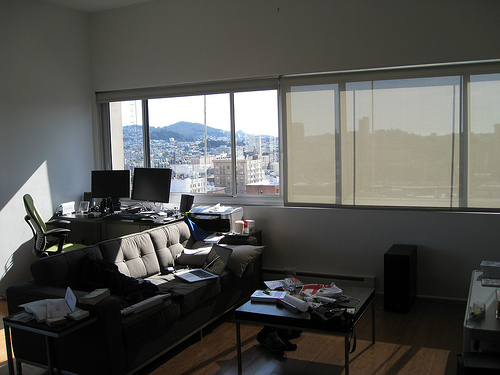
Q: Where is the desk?
A: By the window.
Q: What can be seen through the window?
A: The city.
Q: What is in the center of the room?
A: A coffee table.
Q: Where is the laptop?
A: On the couch.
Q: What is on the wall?
A: Windows.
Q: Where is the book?
A: On the table.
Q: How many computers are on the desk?
A: Two.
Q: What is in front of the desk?
A: A chair.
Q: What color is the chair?
A: Green.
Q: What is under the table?
A: Shoes.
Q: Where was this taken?
A: Living room.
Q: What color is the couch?
A: Black.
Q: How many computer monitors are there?
A: 2.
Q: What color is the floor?
A: Brown.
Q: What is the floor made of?
A: Wood.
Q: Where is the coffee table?
A: In front of the couch.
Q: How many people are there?
A: 0.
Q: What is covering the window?
A: Shade.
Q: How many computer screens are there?
A: Two.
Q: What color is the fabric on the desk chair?
A: Green.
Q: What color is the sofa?
A: Brown.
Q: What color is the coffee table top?
A: Black.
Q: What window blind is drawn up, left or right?
A: Left.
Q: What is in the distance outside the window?
A: Mountains.